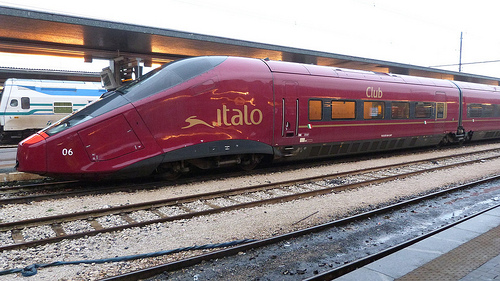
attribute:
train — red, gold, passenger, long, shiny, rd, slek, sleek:
[37, 80, 497, 144]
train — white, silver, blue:
[12, 74, 81, 109]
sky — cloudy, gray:
[329, 17, 358, 37]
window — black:
[140, 66, 192, 91]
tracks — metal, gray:
[208, 177, 227, 204]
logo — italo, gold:
[211, 100, 273, 135]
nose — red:
[48, 71, 244, 159]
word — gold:
[365, 84, 387, 102]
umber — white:
[51, 147, 80, 158]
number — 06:
[62, 140, 71, 155]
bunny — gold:
[173, 113, 213, 134]